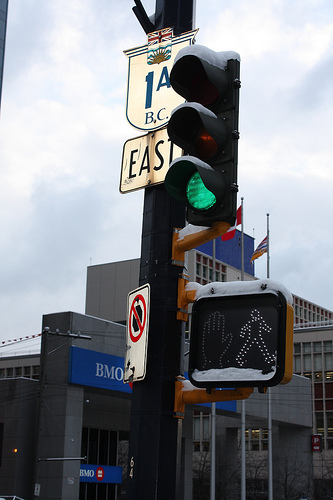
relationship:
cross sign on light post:
[188, 279, 294, 395] [125, 0, 194, 500]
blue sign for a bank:
[79, 464, 122, 483] [3, 309, 315, 496]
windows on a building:
[313, 338, 322, 443] [83, 250, 322, 489]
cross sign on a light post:
[188, 279, 294, 395] [125, 0, 194, 500]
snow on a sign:
[185, 279, 293, 305] [184, 279, 291, 404]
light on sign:
[178, 168, 221, 213] [164, 43, 243, 257]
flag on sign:
[144, 28, 171, 46] [115, 21, 208, 200]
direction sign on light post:
[119, 128, 182, 194] [125, 0, 194, 500]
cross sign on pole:
[188, 279, 294, 395] [129, 0, 201, 495]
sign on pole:
[164, 43, 243, 257] [133, 7, 193, 493]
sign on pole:
[124, 282, 151, 383] [133, 7, 193, 493]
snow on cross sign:
[186, 275, 297, 304] [188, 279, 294, 395]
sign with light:
[164, 43, 243, 257] [186, 171, 216, 210]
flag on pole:
[215, 205, 247, 238] [236, 200, 250, 275]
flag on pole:
[250, 225, 273, 266] [261, 211, 274, 276]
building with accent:
[78, 184, 328, 426] [200, 225, 253, 264]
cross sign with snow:
[188, 279, 294, 395] [198, 273, 263, 299]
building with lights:
[85, 249, 333, 451] [246, 425, 267, 439]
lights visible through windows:
[246, 425, 267, 439] [234, 428, 273, 458]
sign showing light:
[164, 43, 243, 257] [164, 155, 224, 227]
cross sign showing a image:
[188, 279, 294, 395] [235, 309, 273, 367]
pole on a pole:
[265, 209, 272, 281] [238, 191, 252, 281]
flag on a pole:
[221, 205, 242, 242] [238, 191, 252, 281]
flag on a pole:
[250, 236, 268, 265] [265, 209, 272, 281]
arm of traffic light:
[166, 224, 226, 271] [170, 39, 245, 238]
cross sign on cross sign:
[188, 279, 294, 395] [189, 301, 281, 388]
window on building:
[314, 371, 322, 381] [276, 324, 331, 485]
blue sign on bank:
[79, 464, 122, 483] [0, 310, 315, 500]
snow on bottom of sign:
[185, 279, 293, 305] [184, 283, 288, 385]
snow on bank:
[69, 305, 125, 334] [0, 310, 315, 500]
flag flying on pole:
[250, 236, 268, 265] [264, 210, 271, 280]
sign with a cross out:
[124, 282, 151, 383] [127, 290, 148, 339]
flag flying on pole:
[221, 205, 242, 242] [235, 201, 248, 282]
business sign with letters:
[68, 346, 237, 414] [93, 359, 129, 384]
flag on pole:
[221, 205, 242, 242] [237, 197, 250, 498]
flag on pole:
[250, 236, 268, 265] [263, 211, 275, 497]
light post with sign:
[126, 0, 196, 498] [119, 279, 154, 384]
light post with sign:
[126, 0, 196, 498] [117, 128, 188, 194]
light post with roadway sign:
[126, 0, 196, 498] [123, 27, 200, 132]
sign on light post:
[164, 43, 243, 257] [125, 0, 194, 500]